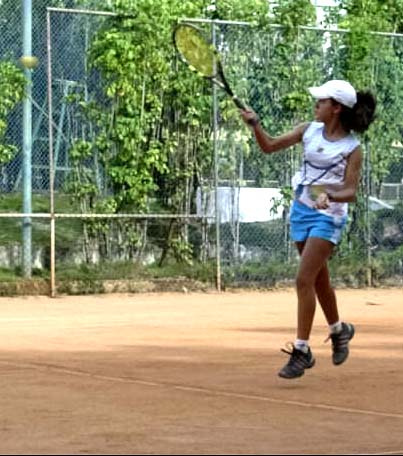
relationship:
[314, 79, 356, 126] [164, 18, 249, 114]
head holding racket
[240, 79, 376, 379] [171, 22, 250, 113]
person holding racket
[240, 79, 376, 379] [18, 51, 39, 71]
person hitting ball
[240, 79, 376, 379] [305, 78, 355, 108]
person wearing cap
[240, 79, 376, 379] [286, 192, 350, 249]
person wearing shorts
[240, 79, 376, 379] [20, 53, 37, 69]
person hit ball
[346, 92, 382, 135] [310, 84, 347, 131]
hair up behind head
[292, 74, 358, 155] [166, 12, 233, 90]
person holding tennis racket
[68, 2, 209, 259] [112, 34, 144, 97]
plant with leaves